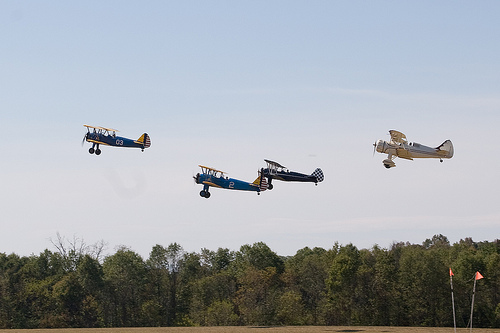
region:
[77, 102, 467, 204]
planes in the sky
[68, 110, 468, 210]
a group of four planes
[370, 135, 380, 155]
propeller on the front of the plane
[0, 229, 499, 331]
a row of dark green trees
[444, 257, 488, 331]
two skinny poles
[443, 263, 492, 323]
small red flags on the poles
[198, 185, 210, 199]
front wheels are down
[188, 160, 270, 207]
blue and yellow paint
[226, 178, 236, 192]
number 2 on the side of the plane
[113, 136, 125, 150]
numbers on the side of the plane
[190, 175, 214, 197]
Blue and yellow plane in the sky.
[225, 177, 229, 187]
Blue and yellow plane in the sky.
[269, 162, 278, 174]
Blue and yellow plane in the sky.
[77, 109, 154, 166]
Blue and yellow plane in the sky.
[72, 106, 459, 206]
planes in the sky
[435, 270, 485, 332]
two flags are together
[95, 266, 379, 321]
the trees are large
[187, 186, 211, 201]
wheels of the plane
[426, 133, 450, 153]
tail of the plane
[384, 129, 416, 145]
wing of the plane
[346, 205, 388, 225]
few clouds in sky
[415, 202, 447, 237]
the sky is lightly slightly blue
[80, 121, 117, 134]
top of the plane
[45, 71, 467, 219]
the charter planes are flying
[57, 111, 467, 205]
the charter planes are flying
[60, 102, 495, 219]
the charter planes are flying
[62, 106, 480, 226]
the charter planes are flying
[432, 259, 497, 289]
the two orange flags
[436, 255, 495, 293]
the two orange flags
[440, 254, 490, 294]
the two orange flags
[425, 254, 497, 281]
the two orange flags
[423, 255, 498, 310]
the two orange flags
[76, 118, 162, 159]
A blue and yellow plane flying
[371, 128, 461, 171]
A white plane in the sky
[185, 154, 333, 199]
Two planes flying next to one another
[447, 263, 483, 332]
Two flagpoles standing on the ground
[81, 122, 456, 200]
Four stunt planes gather in the sky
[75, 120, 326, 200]
A plane flying ahead of two other stunt planes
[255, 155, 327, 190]
A black stunt plane flying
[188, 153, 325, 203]
A black plane flying behind and blue plane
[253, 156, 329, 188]
A black plane with a checkered stablizer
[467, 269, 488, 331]
A flag in front of a group of trees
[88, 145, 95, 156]
black tire on plane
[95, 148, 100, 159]
black tire on plane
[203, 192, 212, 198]
black tire on plane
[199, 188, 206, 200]
black tire on plane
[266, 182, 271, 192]
black tire on plane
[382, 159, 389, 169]
black tire on plane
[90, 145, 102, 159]
black tires on plane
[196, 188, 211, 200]
black tires on plane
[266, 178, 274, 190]
black tires on plane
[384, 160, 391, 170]
black tires on plane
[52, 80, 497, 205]
airplanes in the background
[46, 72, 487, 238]
airplanes in the sky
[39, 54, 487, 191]
four airplanes in the sky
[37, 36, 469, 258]
clear bright sky in he background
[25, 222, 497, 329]
many trees in the background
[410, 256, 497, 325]
flag in the background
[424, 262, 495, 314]
two flags in the background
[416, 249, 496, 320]
two flagpoles in he background